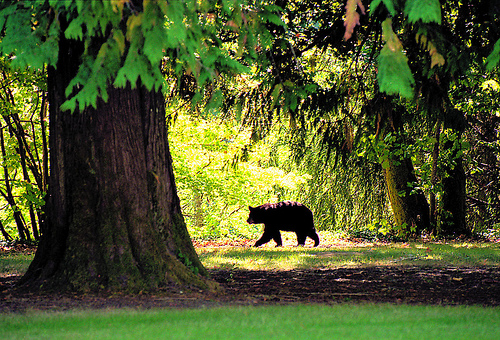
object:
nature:
[185, 177, 360, 247]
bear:
[246, 200, 322, 249]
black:
[268, 215, 292, 226]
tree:
[0, 0, 298, 305]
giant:
[138, 112, 158, 257]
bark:
[70, 113, 109, 209]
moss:
[84, 164, 105, 180]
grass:
[0, 302, 499, 338]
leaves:
[379, 23, 445, 68]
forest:
[0, 0, 499, 340]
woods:
[389, 158, 431, 239]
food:
[193, 242, 243, 249]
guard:
[255, 227, 269, 247]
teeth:
[249, 218, 254, 224]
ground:
[198, 246, 500, 308]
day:
[0, 0, 499, 340]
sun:
[156, 102, 321, 204]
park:
[0, 0, 500, 339]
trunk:
[15, 34, 211, 299]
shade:
[224, 260, 500, 312]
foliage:
[4, 0, 499, 114]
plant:
[364, 216, 418, 240]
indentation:
[54, 133, 93, 207]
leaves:
[327, 226, 371, 246]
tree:
[0, 54, 44, 256]